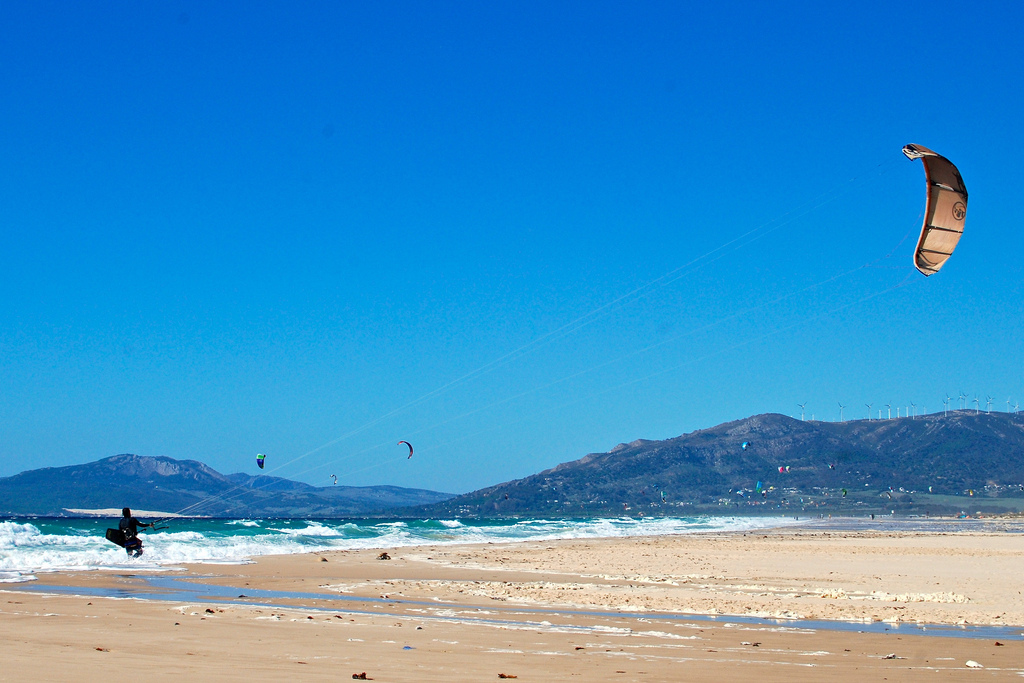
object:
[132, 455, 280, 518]
mountain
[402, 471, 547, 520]
tree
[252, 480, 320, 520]
leaves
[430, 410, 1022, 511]
mountain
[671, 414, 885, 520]
grass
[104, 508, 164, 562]
person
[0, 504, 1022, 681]
beach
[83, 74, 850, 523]
sky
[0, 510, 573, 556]
water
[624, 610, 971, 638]
stream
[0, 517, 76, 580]
wave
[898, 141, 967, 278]
kite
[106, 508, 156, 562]
surfer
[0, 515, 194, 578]
ocean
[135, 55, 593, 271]
sky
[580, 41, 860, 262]
no clouds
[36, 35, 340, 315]
sky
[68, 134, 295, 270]
sky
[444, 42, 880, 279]
no clouds